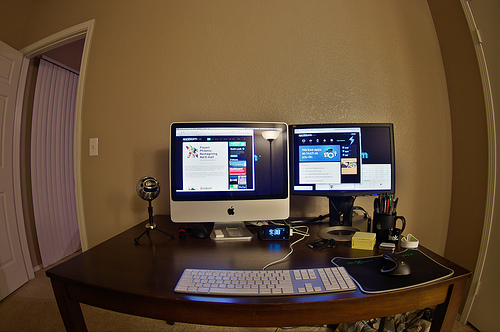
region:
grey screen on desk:
[140, 102, 285, 222]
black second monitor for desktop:
[303, 118, 423, 204]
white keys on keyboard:
[181, 248, 348, 301]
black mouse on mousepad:
[376, 249, 413, 276]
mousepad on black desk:
[351, 253, 431, 289]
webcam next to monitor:
[119, 157, 170, 224]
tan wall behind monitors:
[193, 1, 339, 113]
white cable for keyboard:
[251, 223, 293, 276]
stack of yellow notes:
[342, 225, 370, 249]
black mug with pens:
[372, 185, 404, 237]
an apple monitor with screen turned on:
[168, 120, 288, 217]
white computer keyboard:
[177, 263, 357, 296]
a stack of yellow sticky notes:
[350, 228, 375, 254]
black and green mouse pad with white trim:
[335, 248, 456, 293]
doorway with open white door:
[0, 12, 102, 317]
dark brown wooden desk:
[45, 213, 471, 328]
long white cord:
[262, 216, 310, 273]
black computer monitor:
[289, 123, 396, 221]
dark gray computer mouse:
[393, 263, 411, 275]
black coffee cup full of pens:
[368, 192, 405, 234]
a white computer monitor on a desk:
[168, 123, 290, 222]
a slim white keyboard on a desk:
[174, 267, 354, 294]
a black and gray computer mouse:
[377, 250, 412, 277]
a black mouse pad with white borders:
[331, 248, 451, 289]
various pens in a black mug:
[373, 193, 406, 239]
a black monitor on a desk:
[290, 124, 395, 195]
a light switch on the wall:
[89, 137, 99, 157]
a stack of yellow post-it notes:
[351, 231, 377, 249]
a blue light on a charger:
[267, 225, 284, 238]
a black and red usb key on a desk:
[177, 226, 186, 239]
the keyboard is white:
[191, 266, 341, 293]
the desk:
[109, 252, 157, 285]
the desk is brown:
[115, 249, 169, 296]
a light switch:
[84, 134, 103, 156]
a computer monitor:
[174, 127, 286, 204]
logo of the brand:
[222, 204, 237, 219]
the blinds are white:
[37, 109, 67, 203]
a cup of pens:
[374, 192, 392, 213]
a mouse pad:
[361, 270, 387, 287]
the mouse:
[386, 249, 407, 276]